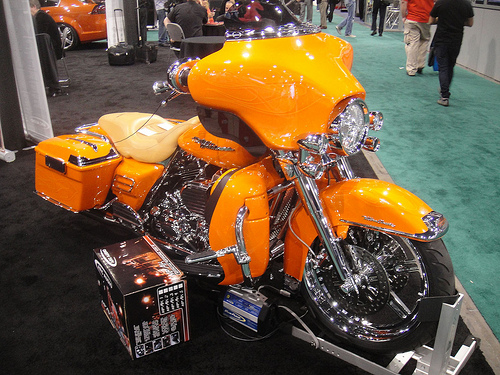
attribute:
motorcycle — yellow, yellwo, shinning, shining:
[36, 24, 463, 361]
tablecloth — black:
[171, 35, 220, 48]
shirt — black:
[431, 1, 469, 50]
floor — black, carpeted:
[25, 269, 97, 348]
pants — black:
[436, 44, 464, 110]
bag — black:
[104, 32, 136, 65]